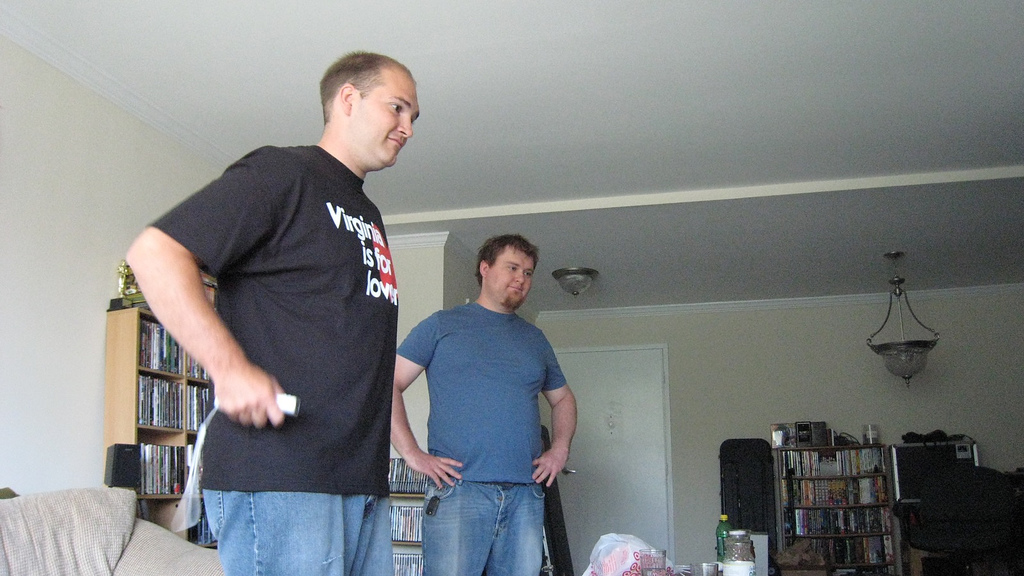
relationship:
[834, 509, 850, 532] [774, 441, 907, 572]
book on book shelf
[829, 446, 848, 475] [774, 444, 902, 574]
movie on book shelf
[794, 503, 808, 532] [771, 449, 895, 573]
movie on a shelf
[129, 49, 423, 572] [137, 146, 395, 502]
man wears t shirt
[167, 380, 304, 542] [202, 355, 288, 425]
wii remote in hand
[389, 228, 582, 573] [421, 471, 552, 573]
man wears jeans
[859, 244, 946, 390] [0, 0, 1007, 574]
light fixture in living room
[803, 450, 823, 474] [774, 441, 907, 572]
book on book shelf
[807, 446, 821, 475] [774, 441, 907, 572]
book on book shelf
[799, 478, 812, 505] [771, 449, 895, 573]
movie on shelf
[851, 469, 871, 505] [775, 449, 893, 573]
book on book shelf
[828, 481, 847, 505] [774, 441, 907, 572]
book on book shelf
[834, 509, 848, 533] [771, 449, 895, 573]
movie on shelf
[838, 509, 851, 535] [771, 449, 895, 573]
movie on shelf